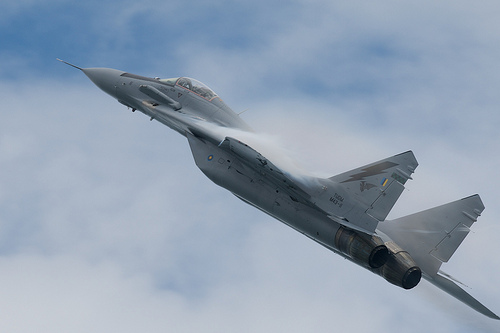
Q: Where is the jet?
A: In the sky.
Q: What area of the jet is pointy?
A: The tip.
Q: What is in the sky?
A: Plane.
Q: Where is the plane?
A: In sky.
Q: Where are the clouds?
A: In sky.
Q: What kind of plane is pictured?
A: Jet.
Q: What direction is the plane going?
A: Up.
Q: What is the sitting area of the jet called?
A: Cockpit.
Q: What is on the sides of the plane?
A: Wings.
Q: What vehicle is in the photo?
A: A plane.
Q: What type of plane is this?
A: Fighter jet.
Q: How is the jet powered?
A: Jet engines.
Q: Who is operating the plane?
A: The pilot.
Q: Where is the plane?
A: In the sky.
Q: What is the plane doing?
A: Flying.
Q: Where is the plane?
A: In the sky.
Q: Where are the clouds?
A: In the sky.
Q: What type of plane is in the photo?
A: A military plane.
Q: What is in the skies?
A: A plane.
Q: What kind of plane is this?
A: Military plane.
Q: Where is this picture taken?
A: In the sky.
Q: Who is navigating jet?
A: Pilot.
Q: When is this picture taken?
A: Daytime.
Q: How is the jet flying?
A: Diagonally.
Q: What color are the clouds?
A: White.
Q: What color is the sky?
A: Blue.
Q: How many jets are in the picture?
A: One.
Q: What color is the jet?
A: Grey.